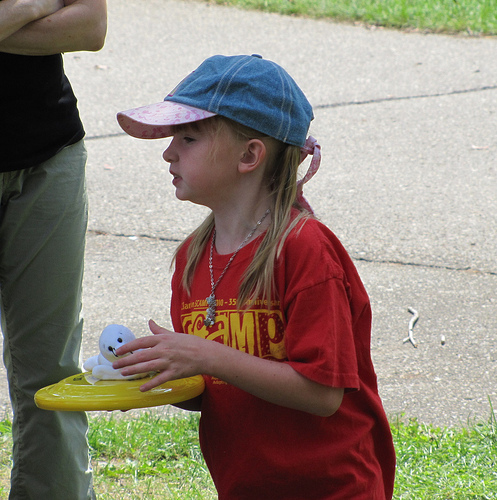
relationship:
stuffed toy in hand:
[84, 323, 150, 379] [111, 318, 210, 391]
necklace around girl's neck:
[202, 264, 219, 327] [210, 196, 258, 242]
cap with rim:
[116, 54, 321, 215] [116, 100, 216, 139]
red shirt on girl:
[172, 194, 401, 499] [111, 53, 396, 498]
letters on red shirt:
[174, 296, 307, 391] [172, 194, 401, 499]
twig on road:
[397, 304, 422, 351] [77, 10, 495, 419]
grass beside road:
[1, 406, 496, 496] [0, 1, 495, 428]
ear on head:
[236, 137, 267, 173] [161, 53, 313, 207]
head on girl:
[161, 53, 313, 207] [111, 53, 396, 498]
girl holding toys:
[80, 46, 436, 482] [34, 315, 207, 407]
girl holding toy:
[111, 53, 396, 498] [30, 321, 209, 414]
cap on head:
[117, 54, 313, 150] [115, 51, 315, 208]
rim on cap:
[116, 100, 216, 139] [116, 54, 321, 215]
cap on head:
[116, 54, 321, 215] [160, 49, 312, 208]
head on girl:
[160, 49, 312, 208] [111, 53, 396, 498]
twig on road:
[397, 288, 432, 359] [0, 1, 495, 428]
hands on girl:
[109, 314, 201, 395] [111, 53, 396, 498]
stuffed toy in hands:
[84, 323, 150, 379] [109, 314, 201, 395]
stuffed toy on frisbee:
[79, 320, 143, 384] [30, 366, 201, 414]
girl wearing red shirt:
[111, 53, 396, 498] [152, 208, 400, 499]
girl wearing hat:
[111, 53, 396, 498] [136, 56, 328, 143]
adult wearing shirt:
[0, 1, 110, 498] [0, 49, 85, 172]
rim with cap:
[116, 100, 216, 139] [109, 48, 322, 164]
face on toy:
[101, 332, 132, 357] [71, 306, 156, 387]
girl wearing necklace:
[111, 53, 396, 498] [206, 208, 277, 323]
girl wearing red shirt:
[111, 53, 396, 498] [172, 194, 401, 499]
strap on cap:
[293, 134, 326, 200] [113, 46, 315, 148]